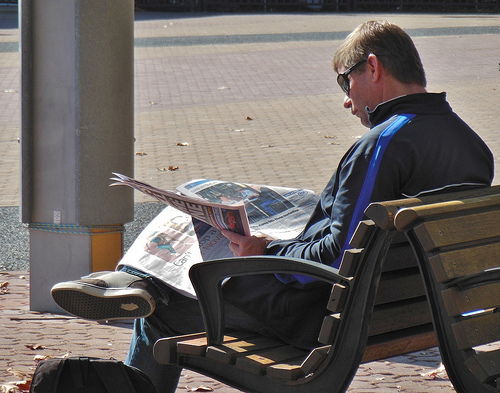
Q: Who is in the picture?
A: A man.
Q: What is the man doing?
A: Reading.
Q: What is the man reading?
A: The paper.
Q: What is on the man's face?
A: Sunglasses.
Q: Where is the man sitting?
A: A bench.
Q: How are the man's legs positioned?
A: Ankle over knee.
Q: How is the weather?
A: Sunny.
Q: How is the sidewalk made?
A: Of brick.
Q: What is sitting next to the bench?
A: A backpack.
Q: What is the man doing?
A: Reading a newspaper.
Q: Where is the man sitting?
A: On a bench.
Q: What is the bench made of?
A: Wood.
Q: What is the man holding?
A: A newspaper.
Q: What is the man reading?
A: A newspaper.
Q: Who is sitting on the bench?
A: Man with sunglasses.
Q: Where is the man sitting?
A: On bench.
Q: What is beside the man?
A: Backpack.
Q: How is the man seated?
A: With right leg on the left leg.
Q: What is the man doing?
A: Reading.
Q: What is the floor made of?
A: Concrete.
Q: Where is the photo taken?
A: Park.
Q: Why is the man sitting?
A: Resting.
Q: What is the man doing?
A: Reading the newspaper.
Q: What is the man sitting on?
A: A bench.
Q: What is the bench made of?
A: Metal and wood.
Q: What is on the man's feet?
A: Gray shoes.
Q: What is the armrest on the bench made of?
A: Metal.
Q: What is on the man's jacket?
A: A blue stripe.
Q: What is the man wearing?
A: A windbreaker.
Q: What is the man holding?
A: A newspaper.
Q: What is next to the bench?
A: A bench.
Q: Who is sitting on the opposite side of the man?
A: No one.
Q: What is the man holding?
A: A newspaper.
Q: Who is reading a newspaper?
A: The man.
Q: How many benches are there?
A: 2.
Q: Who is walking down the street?
A: No one.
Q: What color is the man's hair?
A: Brown.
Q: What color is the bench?
A: Black and brown.